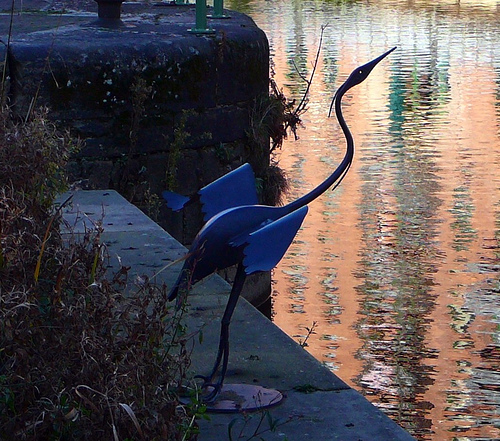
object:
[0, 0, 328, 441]
brush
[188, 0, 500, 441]
reflections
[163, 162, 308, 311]
ledge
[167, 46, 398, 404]
bird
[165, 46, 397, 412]
statue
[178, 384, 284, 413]
base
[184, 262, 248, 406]
leg